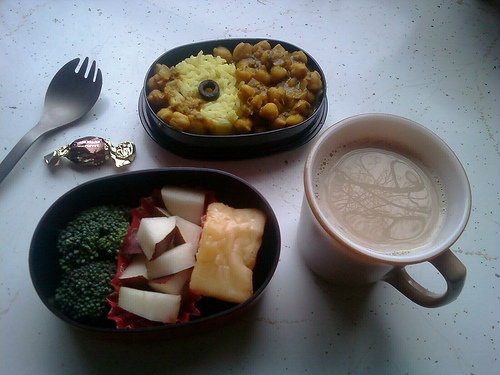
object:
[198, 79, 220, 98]
olive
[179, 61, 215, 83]
rice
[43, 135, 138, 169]
candy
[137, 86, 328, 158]
dish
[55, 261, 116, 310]
vegetables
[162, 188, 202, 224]
potato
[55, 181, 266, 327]
food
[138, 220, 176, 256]
apple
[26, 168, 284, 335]
bowl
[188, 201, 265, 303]
cheese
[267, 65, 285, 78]
beans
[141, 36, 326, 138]
bowl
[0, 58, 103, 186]
spork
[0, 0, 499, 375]
table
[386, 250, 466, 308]
handle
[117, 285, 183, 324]
fruit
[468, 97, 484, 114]
dots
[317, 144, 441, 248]
coffee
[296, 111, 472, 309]
coffee mug